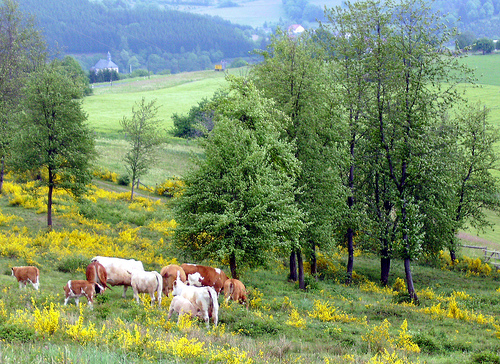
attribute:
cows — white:
[9, 247, 252, 344]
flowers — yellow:
[0, 289, 69, 336]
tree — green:
[118, 90, 165, 207]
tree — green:
[176, 66, 303, 287]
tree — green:
[243, 29, 360, 288]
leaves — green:
[220, 137, 255, 164]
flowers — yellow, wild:
[308, 297, 364, 323]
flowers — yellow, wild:
[360, 315, 392, 345]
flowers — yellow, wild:
[416, 294, 496, 329]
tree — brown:
[401, 259, 423, 305]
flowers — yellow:
[60, 213, 161, 250]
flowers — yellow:
[307, 297, 359, 322]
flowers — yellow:
[404, 295, 494, 325]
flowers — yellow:
[0, 295, 106, 338]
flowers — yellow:
[82, 180, 164, 212]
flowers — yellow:
[0, 206, 179, 268]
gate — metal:
[482, 247, 499, 270]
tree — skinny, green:
[113, 95, 173, 200]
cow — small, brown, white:
[160, 280, 223, 322]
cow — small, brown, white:
[62, 274, 97, 299]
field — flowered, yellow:
[6, 168, 487, 352]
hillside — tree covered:
[19, 7, 249, 160]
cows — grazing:
[79, 251, 262, 325]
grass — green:
[420, 329, 471, 353]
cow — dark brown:
[181, 256, 249, 301]